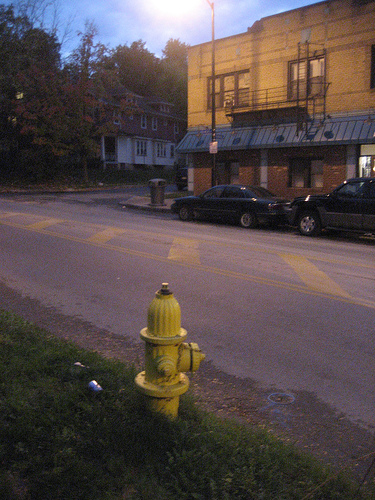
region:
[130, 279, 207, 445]
a yellow fire hydrant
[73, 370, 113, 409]
a drink can on the ground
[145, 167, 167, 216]
a garbage can on a sidewalk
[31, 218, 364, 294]
yellow lines painted on a road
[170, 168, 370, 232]
two cars parked at the curb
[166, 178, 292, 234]
a car parked on the side of street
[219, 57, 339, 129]
a balcony on a building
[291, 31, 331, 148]
a fire escape ladder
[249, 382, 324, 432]
blue paint markings on a road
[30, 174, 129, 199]
brown leaves on the ground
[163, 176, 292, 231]
THIS IS A CAR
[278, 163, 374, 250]
THIS IS A TRUCK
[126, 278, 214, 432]
THIS IS A HYDRANT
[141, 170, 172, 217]
THIS IS A TRASH CAN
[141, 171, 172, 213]
THE TRASH CAN IS GREY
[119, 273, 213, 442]
THE HYDRANT IS YELLOW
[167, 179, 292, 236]
THE CAR IS BLACK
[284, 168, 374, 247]
THE TRUCK IS BLACK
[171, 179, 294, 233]
THE CAR IS PARKED IN FRONT OF THE TRUCK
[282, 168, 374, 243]
THE TRUCK IS PARKED BEHIND THE CAR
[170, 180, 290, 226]
This car on the road is black.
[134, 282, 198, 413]
The fire hydrant on the street is yellow.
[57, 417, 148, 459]
There is grass in the forefront.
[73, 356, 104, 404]
There is trash in the grass.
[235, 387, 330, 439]
The street is damp.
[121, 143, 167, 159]
The side of the house is white.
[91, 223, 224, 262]
There is yellow markers in the street.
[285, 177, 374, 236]
The truck in the street is black.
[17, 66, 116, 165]
The tree has red buds.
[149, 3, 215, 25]
The street lamp is shining.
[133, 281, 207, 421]
A yellow fire hydrant.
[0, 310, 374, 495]
Grass on side of road.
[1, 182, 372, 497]
A street made of asphalt.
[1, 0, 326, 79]
A clear blue sky.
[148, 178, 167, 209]
A trashcan on the sidewalk.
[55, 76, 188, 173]
A house in the trees.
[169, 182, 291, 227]
A black parked car.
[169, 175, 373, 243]
Two black parked cars.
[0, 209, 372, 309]
Yellow lines in the road.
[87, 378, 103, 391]
A can in the grass.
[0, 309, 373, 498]
The green grass.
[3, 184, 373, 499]
The road with yellow lines on the ground.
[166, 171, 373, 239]
Parked vehicles.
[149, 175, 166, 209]
A trashcan.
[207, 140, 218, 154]
A street sign.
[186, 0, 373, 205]
A two story brick building.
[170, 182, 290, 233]
A four-doored car.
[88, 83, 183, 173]
A red and white house.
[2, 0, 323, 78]
A blue sky.